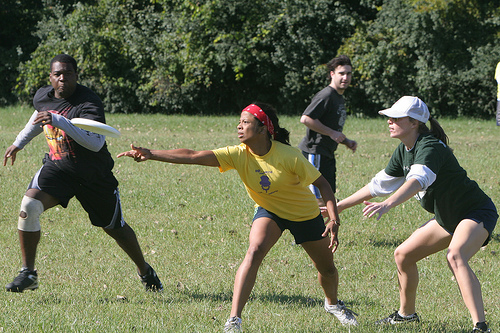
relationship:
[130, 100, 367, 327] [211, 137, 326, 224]
she wearing shirt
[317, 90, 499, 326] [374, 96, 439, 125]
she wearing cap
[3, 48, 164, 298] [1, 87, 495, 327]
man standing field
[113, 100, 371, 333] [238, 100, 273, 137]
she has bandana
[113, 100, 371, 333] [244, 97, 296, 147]
she has hair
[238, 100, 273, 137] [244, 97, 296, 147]
bandana in hair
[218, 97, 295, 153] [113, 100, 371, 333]
head of she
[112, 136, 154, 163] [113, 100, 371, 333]
hand of she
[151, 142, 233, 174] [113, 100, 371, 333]
arm of she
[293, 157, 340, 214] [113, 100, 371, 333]
arm of she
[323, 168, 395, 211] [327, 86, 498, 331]
arm of woman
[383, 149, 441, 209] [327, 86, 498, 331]
arm of woman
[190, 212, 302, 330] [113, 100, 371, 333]
leg of she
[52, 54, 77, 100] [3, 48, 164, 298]
head of man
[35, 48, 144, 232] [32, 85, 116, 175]
man wearing shirt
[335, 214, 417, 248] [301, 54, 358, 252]
grass under body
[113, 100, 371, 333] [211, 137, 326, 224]
she wearing shirt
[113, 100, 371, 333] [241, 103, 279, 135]
she wearing bandana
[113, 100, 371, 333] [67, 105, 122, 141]
she catching frisbee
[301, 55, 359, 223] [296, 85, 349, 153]
body wearing shirt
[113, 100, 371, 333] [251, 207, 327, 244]
she wearing pant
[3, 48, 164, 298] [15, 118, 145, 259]
man wearing shorts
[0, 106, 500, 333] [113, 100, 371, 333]
grass under she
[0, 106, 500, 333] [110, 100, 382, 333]
grass under body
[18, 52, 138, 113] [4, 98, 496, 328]
trees on ground